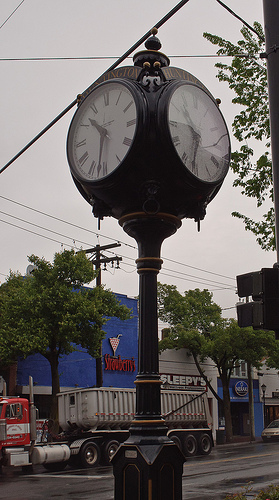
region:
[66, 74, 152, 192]
clock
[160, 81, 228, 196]
black and white clock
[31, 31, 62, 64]
white clouds in blue sky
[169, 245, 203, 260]
white clouds in blue sky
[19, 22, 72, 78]
white clouds in blue sky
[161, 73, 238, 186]
this is a clock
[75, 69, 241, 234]
clock has two faces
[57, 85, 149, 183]
roman numerals on clock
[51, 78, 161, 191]
roman numerals are black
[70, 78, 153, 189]
face of clock is white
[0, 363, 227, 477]
large truck on the street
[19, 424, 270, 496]
the street is wet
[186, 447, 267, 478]
yellow line on street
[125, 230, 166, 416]
black pole of clock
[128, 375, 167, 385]
silver bottom of pole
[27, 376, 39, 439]
silver muffler on back of truck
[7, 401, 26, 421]
window on side of truck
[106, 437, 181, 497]
black base of light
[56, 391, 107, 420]
grey bed of truck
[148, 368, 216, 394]
sign on side of building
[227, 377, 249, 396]
sign on side of building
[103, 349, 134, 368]
red sign on building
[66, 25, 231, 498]
A public clock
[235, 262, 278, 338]
The side view of a cross walk sign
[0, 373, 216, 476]
A red semi truck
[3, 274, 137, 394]
A blue building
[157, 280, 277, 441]
A tree on the sidewalk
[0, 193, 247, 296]
Telephone wires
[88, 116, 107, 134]
An hour hand in a clock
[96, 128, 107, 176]
A minute hand in a clock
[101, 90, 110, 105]
A roman numeral twelve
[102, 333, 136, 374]
A restaurant sign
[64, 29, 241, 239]
ORNATE CLOCK ON ROADWAY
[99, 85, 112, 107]
ROMAN NUMBER 12 ON CLOCK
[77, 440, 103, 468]
WHEEL OF NEARBY TRUCK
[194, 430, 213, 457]
WHEEL OF NEARBY TRUCK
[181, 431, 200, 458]
TIRE OF NEARBY TRUCK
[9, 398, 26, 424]
SIDEVIEW MIRROR OF NEARBY TRUCK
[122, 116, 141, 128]
ROMAN NUMBER 3 ON CLOCK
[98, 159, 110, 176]
ROMAN NUMBER 6 ON CLOCK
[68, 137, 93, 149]
ROMAN NUMBER 9 ON CLOCK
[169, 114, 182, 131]
ROMAN NUMBER 9 ON CLOCK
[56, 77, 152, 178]
clock has white face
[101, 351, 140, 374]
logo on side of building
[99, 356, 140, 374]
logo is red in color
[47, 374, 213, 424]
truck is carrying white box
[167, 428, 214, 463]
truck has wheels on it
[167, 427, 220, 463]
wheels are touching the ground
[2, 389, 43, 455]
cab of truck is red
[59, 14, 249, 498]
this is a post with a clock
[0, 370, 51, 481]
this is a red and white truck cab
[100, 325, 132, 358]
this is a margarita glass on a sign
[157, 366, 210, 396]
the sign says "sleepy's"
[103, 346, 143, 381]
this sign says "Strawberry's"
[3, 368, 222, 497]
this truck is hauling a large trailer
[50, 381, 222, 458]
the trailer is grey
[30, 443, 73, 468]
this is a gas tank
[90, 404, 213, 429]
this is a strip of reflectors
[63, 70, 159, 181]
the clock has Roman numerals